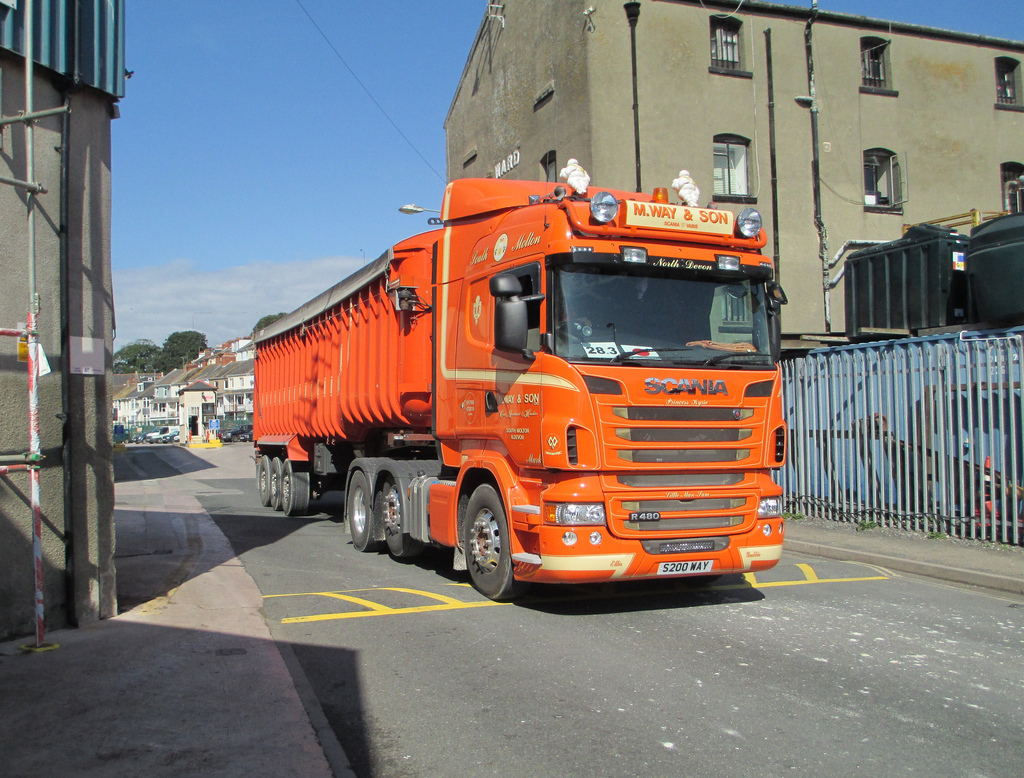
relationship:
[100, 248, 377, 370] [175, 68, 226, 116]
clouds in sky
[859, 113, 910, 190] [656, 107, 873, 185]
window in building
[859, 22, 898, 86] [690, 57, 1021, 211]
window in building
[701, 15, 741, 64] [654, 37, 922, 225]
window on building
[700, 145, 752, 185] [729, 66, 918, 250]
window on building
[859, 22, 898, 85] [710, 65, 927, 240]
window on building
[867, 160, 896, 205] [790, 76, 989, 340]
window on building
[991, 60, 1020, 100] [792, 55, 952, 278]
window on building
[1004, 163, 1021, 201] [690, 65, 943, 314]
window on building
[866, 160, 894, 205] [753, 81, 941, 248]
window on building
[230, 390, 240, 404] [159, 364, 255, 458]
window behind building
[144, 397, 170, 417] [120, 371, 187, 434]
window behind building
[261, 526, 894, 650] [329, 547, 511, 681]
lines painted on road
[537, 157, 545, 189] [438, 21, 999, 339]
window adorning building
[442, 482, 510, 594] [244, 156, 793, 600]
wheel mounted on truck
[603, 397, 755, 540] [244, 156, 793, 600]
grill cooling truck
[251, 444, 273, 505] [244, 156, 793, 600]
wheel mounted on truck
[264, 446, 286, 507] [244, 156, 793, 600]
wheel mounted on truck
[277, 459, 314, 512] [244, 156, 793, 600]
wheel mounted on truck